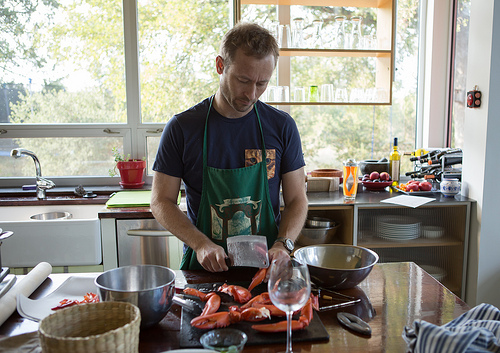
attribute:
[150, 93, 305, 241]
shirt — blue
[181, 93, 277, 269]
apron — green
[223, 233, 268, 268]
meat cleaver — upside down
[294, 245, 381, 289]
bowl — stainless steel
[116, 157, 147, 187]
flower pot — orange, red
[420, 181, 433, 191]
tomato — red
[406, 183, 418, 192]
tomato — red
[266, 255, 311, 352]
wine glass — empty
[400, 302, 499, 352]
towel — striped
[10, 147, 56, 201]
faucet — stainless steel